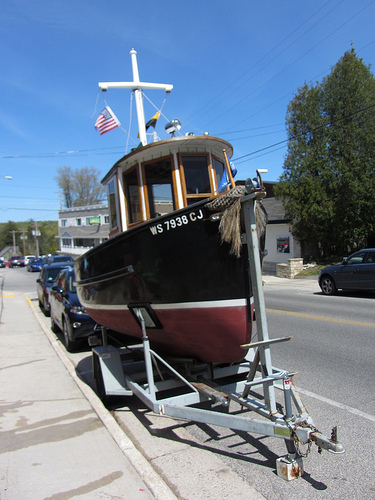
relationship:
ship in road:
[77, 127, 290, 381] [289, 293, 366, 402]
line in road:
[311, 306, 340, 332] [289, 293, 366, 402]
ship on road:
[77, 127, 290, 381] [289, 293, 366, 402]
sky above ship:
[161, 3, 276, 94] [77, 127, 290, 381]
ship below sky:
[77, 127, 290, 381] [161, 3, 276, 94]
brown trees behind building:
[38, 160, 100, 209] [50, 195, 109, 254]